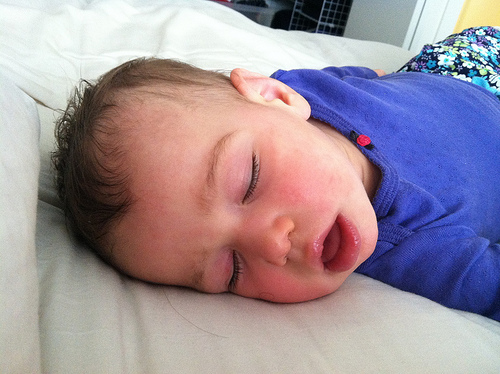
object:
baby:
[52, 24, 498, 323]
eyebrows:
[181, 241, 211, 300]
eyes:
[217, 137, 266, 214]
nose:
[248, 218, 299, 264]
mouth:
[307, 200, 361, 282]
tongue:
[323, 223, 344, 264]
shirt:
[272, 43, 500, 324]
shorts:
[398, 16, 499, 96]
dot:
[352, 129, 374, 151]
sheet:
[0, 2, 499, 371]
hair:
[50, 50, 246, 284]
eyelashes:
[241, 152, 261, 201]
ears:
[227, 61, 327, 120]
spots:
[152, 136, 169, 148]